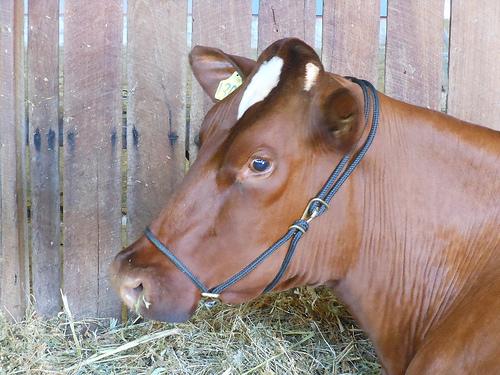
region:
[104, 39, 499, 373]
Brown and white cow.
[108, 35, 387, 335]
Black halter on brown cow.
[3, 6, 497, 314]
Brown wooden fence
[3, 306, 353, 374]
Brown hay on the ground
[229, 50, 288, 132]
White pattern on brown cows face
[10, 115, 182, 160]
Black stains on brown wooden fence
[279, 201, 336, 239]
Gold clasps on black halter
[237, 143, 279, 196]
Black cows eye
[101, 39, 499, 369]
Brown cow looking away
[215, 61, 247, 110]
White tag in cows ear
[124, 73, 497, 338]
A brown cow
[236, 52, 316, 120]
A white spot on the cow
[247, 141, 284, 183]
A cow's eye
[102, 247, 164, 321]
A cow's muzzle in the photo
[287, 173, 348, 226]
A blue strap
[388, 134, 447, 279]
Brown skin of a cow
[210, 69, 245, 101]
An ear tag in the photo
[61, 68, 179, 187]
Wooden fence in the picture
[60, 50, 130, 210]
Timber in the photo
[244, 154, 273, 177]
Eye of a cow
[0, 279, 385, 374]
Hay next to fence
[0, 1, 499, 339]
A wooden fence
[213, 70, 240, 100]
A tag in cows ear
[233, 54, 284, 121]
A white spot in the middle of cows head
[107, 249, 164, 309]
Nose of a cow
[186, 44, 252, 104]
ear of a cow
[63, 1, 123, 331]
A wooden plank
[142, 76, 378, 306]
A blue rope or muzzle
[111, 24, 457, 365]
a beautiful cow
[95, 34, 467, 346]
cows have such beautiful faces!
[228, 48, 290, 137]
the cow has a white blaze on its forehead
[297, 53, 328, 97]
it also has a little speck of white next to its ear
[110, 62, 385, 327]
the cow has a blue halter on it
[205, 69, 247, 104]
the cow has a tag in its ear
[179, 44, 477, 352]
the cow has wrinkles on its neck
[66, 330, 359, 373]
hay is in the stall with her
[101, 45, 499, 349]
the cow is a very pretty brown color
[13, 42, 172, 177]
wood slats form the stall wall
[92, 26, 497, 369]
a cow in front of a fence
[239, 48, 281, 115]
his ear is white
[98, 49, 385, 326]
he is wearing a harness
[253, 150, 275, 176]
the eye is black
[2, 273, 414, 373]
straw on the ground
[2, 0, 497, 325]
the fence is wooden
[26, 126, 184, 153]
black knots on the fence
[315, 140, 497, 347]
wrinkles in his neck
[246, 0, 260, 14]
blue sky through the fence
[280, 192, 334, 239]
a metal clasp on the harness